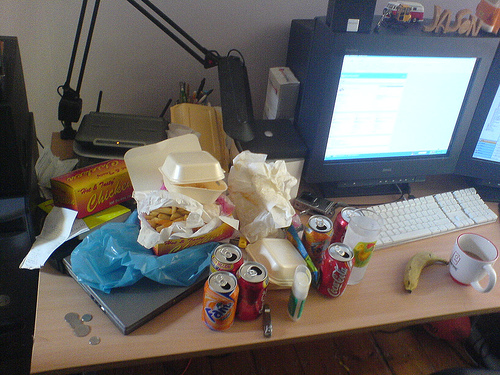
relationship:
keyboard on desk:
[344, 189, 498, 242] [27, 168, 497, 373]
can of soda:
[210, 243, 242, 275] [210, 239, 242, 271]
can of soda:
[318, 243, 354, 298] [314, 237, 358, 302]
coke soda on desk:
[320, 244, 352, 301] [29, 188, 500, 374]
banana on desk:
[397, 252, 450, 292] [27, 139, 497, 373]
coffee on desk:
[458, 228, 494, 293] [29, 188, 500, 374]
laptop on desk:
[63, 256, 206, 332] [27, 168, 497, 373]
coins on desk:
[87, 336, 99, 345] [27, 168, 497, 373]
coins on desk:
[81, 307, 91, 317] [27, 168, 497, 373]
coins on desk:
[63, 312, 78, 320] [27, 168, 497, 373]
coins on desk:
[70, 319, 82, 324] [27, 168, 497, 373]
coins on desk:
[73, 324, 83, 328] [27, 168, 497, 373]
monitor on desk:
[275, 7, 495, 191] [27, 168, 497, 373]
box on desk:
[58, 172, 125, 212] [31, 265, 148, 361]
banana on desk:
[397, 237, 464, 318] [29, 188, 500, 374]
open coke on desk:
[310, 237, 356, 270] [27, 168, 497, 373]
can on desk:
[197, 271, 247, 353] [27, 168, 497, 373]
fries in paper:
[125, 193, 210, 245] [129, 184, 205, 247]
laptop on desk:
[65, 230, 237, 333] [8, 216, 180, 373]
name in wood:
[426, 3, 486, 39] [429, 2, 483, 39]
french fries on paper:
[128, 190, 208, 243] [131, 189, 214, 248]